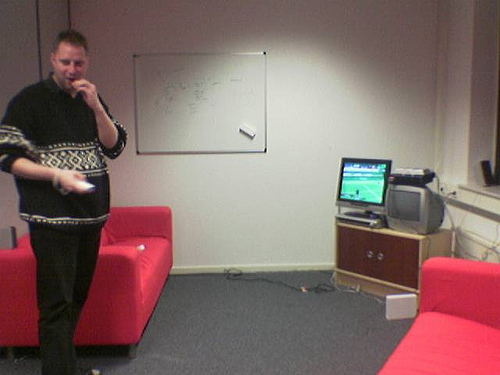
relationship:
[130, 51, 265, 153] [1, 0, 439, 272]
white board on wall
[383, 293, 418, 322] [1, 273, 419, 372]
wii system on floor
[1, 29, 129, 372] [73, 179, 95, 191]
man with controller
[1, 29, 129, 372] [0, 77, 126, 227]
man in a sweater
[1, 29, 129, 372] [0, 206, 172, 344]
man near a red couch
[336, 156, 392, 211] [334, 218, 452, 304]
monitor on cabinet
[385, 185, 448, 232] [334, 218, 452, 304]
televison on a cabinet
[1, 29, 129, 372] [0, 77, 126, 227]
man wearing a sweater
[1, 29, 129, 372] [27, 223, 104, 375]
man in pants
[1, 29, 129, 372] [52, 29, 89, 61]
man with short hair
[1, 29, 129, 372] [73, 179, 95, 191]
man with a controller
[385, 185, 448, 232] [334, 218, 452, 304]
televison on top of cabinet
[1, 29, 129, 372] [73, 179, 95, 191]
man holding controller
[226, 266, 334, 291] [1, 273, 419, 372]
cord on floor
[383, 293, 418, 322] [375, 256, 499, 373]
wii next to a couch